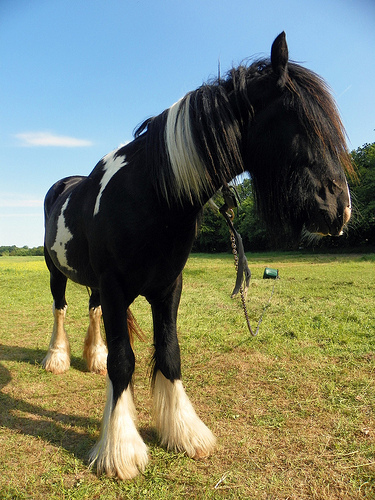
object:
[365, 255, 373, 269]
grass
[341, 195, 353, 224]
nose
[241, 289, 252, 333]
chain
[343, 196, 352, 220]
nose patch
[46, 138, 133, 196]
back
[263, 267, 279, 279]
bucket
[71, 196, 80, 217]
patch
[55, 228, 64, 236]
white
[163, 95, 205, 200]
hair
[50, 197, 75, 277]
spot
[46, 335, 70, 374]
hoof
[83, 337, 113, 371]
hoof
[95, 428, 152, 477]
hoof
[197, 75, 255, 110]
mane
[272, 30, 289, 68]
ear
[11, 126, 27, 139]
cloud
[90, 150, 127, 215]
spot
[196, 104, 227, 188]
chain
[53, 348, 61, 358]
white hair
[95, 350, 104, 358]
white hair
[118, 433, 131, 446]
white hair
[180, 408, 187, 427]
white hair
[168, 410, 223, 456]
hoof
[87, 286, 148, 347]
tail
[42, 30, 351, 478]
horse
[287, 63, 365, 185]
hair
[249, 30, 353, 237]
head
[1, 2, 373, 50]
sky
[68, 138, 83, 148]
cloud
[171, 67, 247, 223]
neck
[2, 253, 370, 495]
field